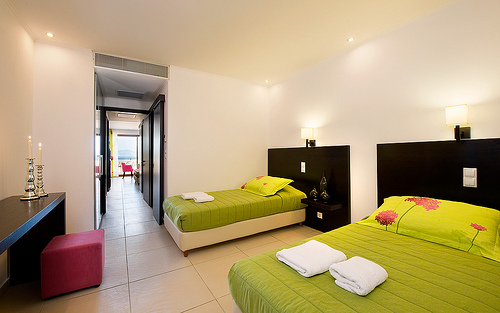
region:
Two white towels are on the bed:
[278, 238, 388, 297]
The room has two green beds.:
[163, 136, 498, 311]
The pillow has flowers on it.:
[378, 185, 499, 265]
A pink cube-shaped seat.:
[43, 230, 103, 299]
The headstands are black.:
[266, 138, 498, 202]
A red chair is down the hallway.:
[121, 160, 132, 174]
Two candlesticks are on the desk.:
[24, 133, 48, 202]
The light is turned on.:
[443, 102, 474, 139]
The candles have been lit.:
[20, 135, 47, 163]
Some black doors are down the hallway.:
[139, 100, 161, 222]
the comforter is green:
[368, 228, 453, 260]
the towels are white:
[333, 255, 381, 291]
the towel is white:
[282, 240, 329, 275]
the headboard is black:
[375, 140, 479, 195]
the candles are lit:
[19, 134, 54, 204]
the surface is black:
[10, 199, 30, 235]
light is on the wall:
[444, 100, 479, 131]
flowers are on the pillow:
[403, 194, 437, 213]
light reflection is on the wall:
[406, 72, 451, 99]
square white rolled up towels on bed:
[273, 237, 390, 297]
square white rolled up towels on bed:
[178, 188, 216, 203]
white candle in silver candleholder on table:
[18, 133, 42, 203]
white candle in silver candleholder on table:
[31, 140, 51, 199]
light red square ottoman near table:
[35, 223, 107, 303]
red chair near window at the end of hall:
[118, 158, 136, 180]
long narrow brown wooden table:
[1, 190, 72, 312]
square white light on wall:
[438, 99, 476, 145]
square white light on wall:
[297, 124, 319, 149]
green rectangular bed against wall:
[225, 190, 498, 311]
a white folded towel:
[327, 250, 391, 302]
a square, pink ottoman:
[40, 228, 111, 305]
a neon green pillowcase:
[240, 165, 292, 201]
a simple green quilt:
[158, 178, 310, 229]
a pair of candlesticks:
[20, 158, 52, 208]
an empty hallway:
[79, 44, 176, 234]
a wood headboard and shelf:
[262, 142, 356, 237]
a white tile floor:
[103, 170, 172, 312]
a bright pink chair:
[118, 160, 132, 181]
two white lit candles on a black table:
[0, 133, 69, 258]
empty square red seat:
[37, 227, 107, 299]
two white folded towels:
[274, 238, 388, 297]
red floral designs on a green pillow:
[354, 192, 499, 263]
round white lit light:
[43, 28, 55, 38]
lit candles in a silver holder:
[21, 132, 47, 200]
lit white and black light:
[440, 100, 473, 140]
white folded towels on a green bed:
[229, 193, 499, 310]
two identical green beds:
[163, 130, 498, 310]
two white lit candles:
[22, 132, 51, 166]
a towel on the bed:
[339, 257, 365, 287]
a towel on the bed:
[196, 187, 215, 207]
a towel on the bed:
[181, 180, 201, 207]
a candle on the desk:
[7, 134, 44, 208]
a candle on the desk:
[32, 140, 57, 191]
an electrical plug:
[455, 156, 495, 187]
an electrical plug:
[290, 156, 318, 181]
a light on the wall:
[440, 88, 476, 148]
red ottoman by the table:
[39, 226, 107, 292]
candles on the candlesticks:
[24, 130, 46, 157]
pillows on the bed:
[241, 171, 495, 251]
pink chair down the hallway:
[119, 160, 134, 177]